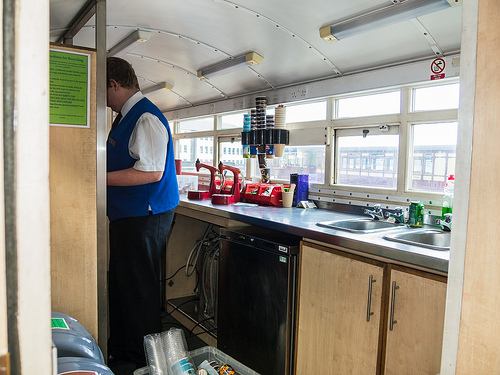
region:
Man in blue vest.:
[100, 40, 180, 368]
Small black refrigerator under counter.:
[207, 223, 294, 373]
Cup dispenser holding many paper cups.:
[239, 95, 290, 165]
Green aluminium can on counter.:
[402, 193, 431, 228]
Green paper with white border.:
[49, 46, 90, 128]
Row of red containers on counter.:
[212, 175, 284, 207]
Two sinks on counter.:
[316, 205, 452, 255]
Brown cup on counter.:
[277, 182, 297, 207]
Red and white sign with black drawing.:
[427, 55, 448, 80]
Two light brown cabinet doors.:
[292, 235, 452, 374]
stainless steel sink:
[311, 195, 405, 240]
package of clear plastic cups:
[127, 320, 192, 374]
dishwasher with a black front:
[191, 223, 309, 372]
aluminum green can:
[393, 193, 433, 251]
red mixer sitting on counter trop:
[211, 155, 246, 217]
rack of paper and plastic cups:
[225, 94, 300, 176]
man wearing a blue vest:
[98, 72, 207, 263]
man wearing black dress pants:
[91, 171, 213, 373]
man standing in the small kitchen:
[101, 50, 172, 359]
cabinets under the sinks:
[304, 240, 449, 371]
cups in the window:
[230, 103, 300, 165]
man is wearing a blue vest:
[101, 103, 200, 225]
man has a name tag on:
[104, 133, 120, 145]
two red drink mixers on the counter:
[186, 150, 241, 210]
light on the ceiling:
[183, 47, 267, 89]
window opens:
[323, 124, 393, 188]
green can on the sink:
[401, 197, 424, 229]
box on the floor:
[133, 312, 235, 365]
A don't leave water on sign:
[418, 50, 452, 89]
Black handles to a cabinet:
[351, 264, 406, 340]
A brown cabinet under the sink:
[293, 233, 390, 374]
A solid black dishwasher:
[213, 213, 295, 373]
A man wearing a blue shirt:
[96, 50, 183, 373]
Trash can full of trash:
[128, 323, 260, 373]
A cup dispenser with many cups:
[230, 93, 301, 162]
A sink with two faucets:
[313, 195, 411, 258]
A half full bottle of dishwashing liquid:
[437, 170, 458, 232]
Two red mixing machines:
[184, 151, 249, 214]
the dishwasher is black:
[222, 255, 282, 327]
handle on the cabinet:
[387, 278, 398, 334]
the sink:
[347, 215, 376, 230]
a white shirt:
[130, 126, 165, 166]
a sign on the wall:
[50, 51, 86, 128]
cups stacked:
[275, 103, 285, 128]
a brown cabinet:
[304, 258, 354, 374]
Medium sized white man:
[97, 53, 176, 373]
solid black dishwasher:
[215, 220, 297, 373]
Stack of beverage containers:
[238, 89, 290, 166]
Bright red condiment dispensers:
[186, 154, 242, 214]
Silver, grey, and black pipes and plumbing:
[171, 215, 226, 337]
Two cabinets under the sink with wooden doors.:
[293, 233, 468, 374]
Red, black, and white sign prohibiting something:
[421, 50, 456, 83]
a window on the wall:
[408, 124, 482, 239]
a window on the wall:
[337, 136, 396, 186]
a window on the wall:
[270, 150, 310, 199]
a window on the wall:
[213, 143, 242, 170]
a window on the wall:
[414, 92, 466, 123]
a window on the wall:
[337, 93, 384, 106]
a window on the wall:
[290, 103, 327, 129]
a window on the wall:
[433, 118, 482, 187]